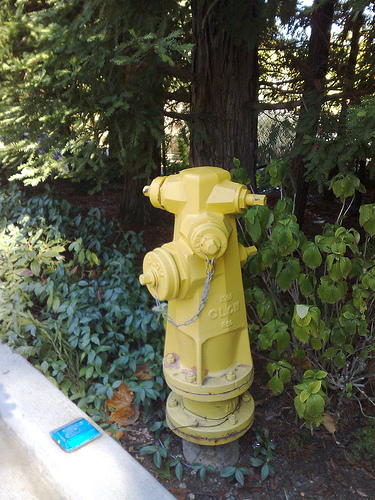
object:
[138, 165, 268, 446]
hydrant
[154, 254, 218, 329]
chain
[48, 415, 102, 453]
reflector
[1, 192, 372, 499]
ground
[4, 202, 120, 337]
leaves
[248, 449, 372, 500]
dirt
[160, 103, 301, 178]
fence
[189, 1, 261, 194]
trees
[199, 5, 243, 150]
trunk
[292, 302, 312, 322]
leaf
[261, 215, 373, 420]
bushes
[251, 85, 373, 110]
branches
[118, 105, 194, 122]
branches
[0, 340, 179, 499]
curb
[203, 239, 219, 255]
valve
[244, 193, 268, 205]
valve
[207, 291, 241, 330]
writing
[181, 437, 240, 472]
base